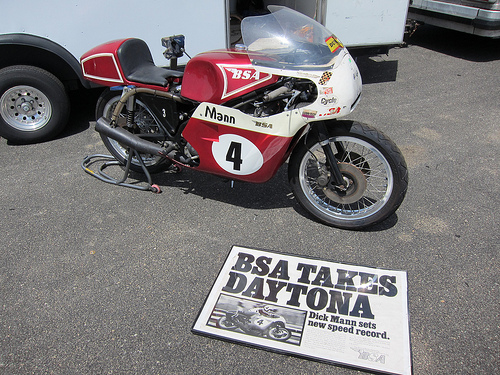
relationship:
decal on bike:
[190, 104, 241, 130] [82, 3, 407, 230]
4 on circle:
[222, 139, 239, 178] [212, 134, 264, 176]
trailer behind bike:
[0, 7, 409, 85] [82, 3, 407, 230]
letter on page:
[237, 253, 253, 275] [193, 246, 412, 374]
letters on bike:
[205, 106, 220, 120] [82, 15, 401, 228]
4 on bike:
[222, 139, 239, 178] [82, 3, 407, 230]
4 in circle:
[222, 139, 239, 178] [214, 134, 253, 176]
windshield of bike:
[237, 17, 336, 69] [82, 3, 407, 230]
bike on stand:
[82, 15, 401, 228] [74, 151, 160, 192]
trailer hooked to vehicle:
[0, 7, 409, 85] [423, 3, 495, 27]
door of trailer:
[229, 5, 312, 49] [0, 7, 409, 85]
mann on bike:
[200, 106, 235, 123] [82, 15, 401, 228]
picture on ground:
[220, 295, 296, 342] [26, 119, 471, 358]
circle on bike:
[214, 134, 253, 176] [82, 3, 407, 230]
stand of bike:
[74, 151, 160, 192] [82, 3, 407, 230]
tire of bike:
[295, 113, 409, 218] [82, 3, 407, 230]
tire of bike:
[94, 83, 179, 164] [82, 3, 407, 230]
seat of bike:
[111, 42, 181, 80] [82, 3, 407, 230]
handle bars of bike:
[255, 79, 296, 109] [82, 3, 407, 230]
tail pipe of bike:
[87, 117, 182, 152] [82, 3, 407, 230]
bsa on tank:
[231, 68, 262, 80] [193, 49, 262, 97]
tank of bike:
[193, 49, 262, 97] [82, 3, 407, 230]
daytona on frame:
[228, 271, 382, 326] [205, 209, 405, 369]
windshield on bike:
[237, 17, 336, 69] [82, 3, 407, 230]